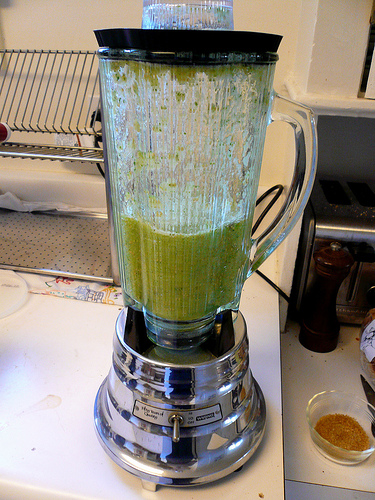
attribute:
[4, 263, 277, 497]
counter — white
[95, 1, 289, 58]
top — black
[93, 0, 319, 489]
blender — hosting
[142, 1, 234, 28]
coveredopening — covered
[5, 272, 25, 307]
lid — clear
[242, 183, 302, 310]
cord — black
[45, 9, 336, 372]
blender — steel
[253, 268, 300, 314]
cord — black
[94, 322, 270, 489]
base — silver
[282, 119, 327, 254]
handle — plastic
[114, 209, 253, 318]
stuff — green